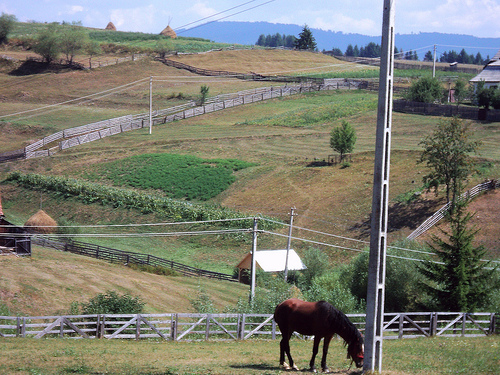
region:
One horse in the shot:
[251, 289, 375, 374]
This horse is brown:
[258, 291, 378, 373]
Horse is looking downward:
[261, 294, 383, 373]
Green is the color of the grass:
[98, 148, 265, 204]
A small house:
[218, 233, 323, 285]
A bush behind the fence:
[61, 287, 156, 346]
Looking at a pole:
[235, 276, 407, 373]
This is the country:
[16, 12, 497, 374]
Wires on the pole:
[3, 7, 408, 86]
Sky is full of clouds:
[293, 5, 498, 40]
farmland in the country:
[8, 14, 498, 373]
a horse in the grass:
[263, 290, 384, 372]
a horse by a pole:
[270, 289, 405, 374]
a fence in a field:
[13, 305, 245, 353]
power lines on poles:
[18, 210, 310, 246]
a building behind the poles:
[233, 241, 306, 285]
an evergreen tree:
[424, 197, 497, 312]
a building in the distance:
[459, 51, 499, 112]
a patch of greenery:
[98, 146, 245, 203]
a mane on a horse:
[315, 298, 365, 343]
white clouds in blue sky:
[176, 0, 208, 16]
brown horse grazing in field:
[260, 290, 360, 360]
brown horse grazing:
[256, 290, 352, 367]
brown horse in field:
[270, 287, 365, 368]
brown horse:
[257, 285, 362, 362]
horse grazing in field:
[260, 295, 371, 356]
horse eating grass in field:
[256, 281, 361, 357]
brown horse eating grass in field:
[277, 292, 375, 372]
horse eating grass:
[265, 295, 368, 367]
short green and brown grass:
[217, 126, 287, 161]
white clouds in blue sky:
[415, 6, 447, 27]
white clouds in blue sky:
[302, 6, 330, 24]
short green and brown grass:
[235, 103, 254, 134]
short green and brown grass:
[277, 170, 317, 196]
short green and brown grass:
[57, 151, 97, 188]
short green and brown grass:
[170, 338, 237, 370]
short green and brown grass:
[63, 340, 105, 356]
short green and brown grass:
[153, 351, 184, 367]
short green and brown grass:
[397, 339, 433, 366]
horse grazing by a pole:
[274, 288, 369, 373]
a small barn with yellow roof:
[241, 237, 313, 288]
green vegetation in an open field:
[38, 163, 258, 242]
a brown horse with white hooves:
[266, 302, 367, 374]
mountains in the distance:
[186, 21, 498, 69]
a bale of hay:
[27, 200, 77, 250]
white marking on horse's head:
[343, 297, 370, 374]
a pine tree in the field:
[426, 194, 498, 331]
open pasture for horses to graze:
[105, 75, 450, 225]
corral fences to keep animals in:
[32, 305, 275, 346]